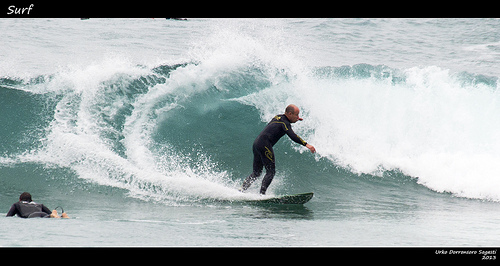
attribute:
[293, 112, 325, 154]
hands — outstretched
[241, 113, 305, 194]
wet suit — black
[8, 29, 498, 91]
foam — white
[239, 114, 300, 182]
wetsuit — black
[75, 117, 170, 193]
wake — created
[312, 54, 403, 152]
wave — crashing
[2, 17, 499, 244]
ocean water — choppy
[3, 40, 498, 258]
waves — white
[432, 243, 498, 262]
caption — white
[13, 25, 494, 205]
water — foamy, white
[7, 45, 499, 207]
wave — large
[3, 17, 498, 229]
waves — trail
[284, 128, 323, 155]
arm — out for balance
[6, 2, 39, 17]
caption — white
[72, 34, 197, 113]
spray — water droplets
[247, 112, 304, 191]
wetsuit — black 